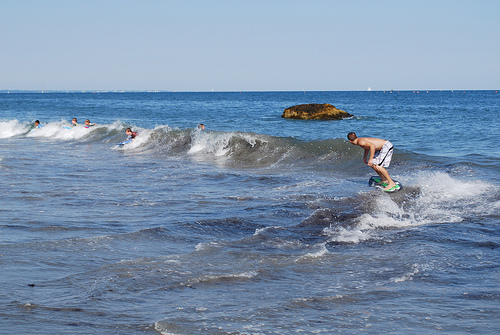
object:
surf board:
[367, 173, 404, 193]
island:
[279, 103, 354, 121]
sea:
[0, 90, 499, 334]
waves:
[0, 113, 499, 305]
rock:
[280, 101, 354, 122]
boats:
[365, 86, 373, 91]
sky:
[0, 0, 499, 91]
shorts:
[370, 140, 395, 169]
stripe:
[376, 145, 395, 166]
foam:
[0, 114, 499, 333]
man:
[346, 131, 397, 190]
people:
[196, 123, 207, 132]